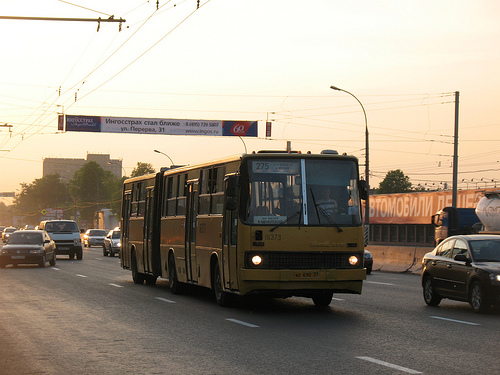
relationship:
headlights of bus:
[248, 251, 371, 266] [115, 153, 368, 301]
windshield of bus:
[253, 163, 362, 225] [115, 153, 368, 301]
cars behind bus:
[13, 226, 115, 274] [115, 153, 368, 301]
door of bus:
[221, 192, 243, 283] [115, 153, 368, 301]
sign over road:
[166, 116, 222, 136] [96, 325, 211, 350]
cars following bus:
[13, 226, 115, 274] [115, 153, 368, 301]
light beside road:
[316, 77, 342, 105] [96, 325, 211, 350]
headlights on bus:
[248, 251, 371, 266] [115, 153, 368, 301]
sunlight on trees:
[28, 123, 60, 132] [66, 169, 118, 198]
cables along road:
[87, 32, 198, 53] [96, 325, 211, 350]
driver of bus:
[280, 181, 306, 223] [115, 153, 368, 301]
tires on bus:
[208, 249, 229, 287] [115, 153, 368, 301]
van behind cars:
[80, 218, 99, 246] [13, 226, 115, 274]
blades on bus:
[281, 209, 336, 227] [115, 153, 368, 301]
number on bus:
[291, 183, 294, 186] [115, 153, 368, 301]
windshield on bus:
[253, 163, 362, 225] [115, 153, 368, 301]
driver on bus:
[280, 181, 306, 223] [115, 153, 368, 301]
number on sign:
[291, 183, 294, 186] [166, 116, 222, 136]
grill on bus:
[289, 253, 295, 256] [115, 153, 368, 301]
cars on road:
[13, 226, 115, 274] [96, 325, 211, 350]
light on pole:
[316, 77, 342, 105] [343, 127, 364, 137]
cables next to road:
[87, 32, 198, 53] [96, 325, 211, 350]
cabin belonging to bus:
[119, 171, 162, 276] [115, 153, 368, 301]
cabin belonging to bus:
[155, 156, 368, 293] [115, 153, 368, 301]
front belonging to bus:
[237, 152, 368, 299] [115, 153, 368, 301]